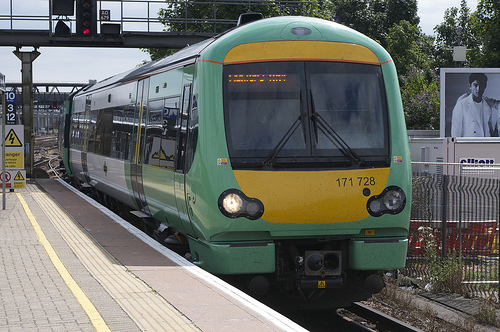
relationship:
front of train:
[223, 39, 394, 221] [58, 15, 414, 310]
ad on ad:
[439, 66, 499, 137] [439, 66, 499, 137]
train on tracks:
[58, 15, 414, 310] [325, 301, 422, 331]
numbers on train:
[333, 174, 378, 187] [58, 15, 414, 310]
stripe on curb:
[14, 189, 112, 331] [0, 242, 166, 331]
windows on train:
[51, 94, 198, 169] [58, 15, 414, 310]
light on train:
[223, 192, 243, 212] [58, 15, 414, 310]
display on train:
[227, 72, 302, 90] [58, 15, 414, 310]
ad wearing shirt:
[439, 66, 499, 137] [450, 94, 492, 137]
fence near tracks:
[411, 161, 499, 303] [325, 301, 422, 331]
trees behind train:
[150, 0, 499, 128] [58, 15, 414, 310]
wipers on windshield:
[261, 88, 361, 169] [224, 62, 391, 171]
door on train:
[128, 77, 149, 213] [58, 15, 414, 310]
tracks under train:
[325, 301, 422, 331] [58, 15, 414, 310]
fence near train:
[411, 161, 499, 303] [58, 15, 414, 310]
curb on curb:
[55, 174, 308, 331] [0, 242, 166, 331]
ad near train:
[439, 66, 499, 137] [58, 15, 414, 310]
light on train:
[383, 186, 402, 210] [58, 15, 414, 310]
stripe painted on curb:
[14, 189, 112, 331] [0, 242, 166, 331]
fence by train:
[411, 161, 499, 303] [58, 15, 414, 310]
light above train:
[82, 27, 91, 36] [58, 15, 414, 310]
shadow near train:
[30, 172, 191, 268] [58, 15, 414, 310]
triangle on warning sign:
[2, 129, 23, 148] [3, 124, 28, 190]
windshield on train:
[224, 62, 391, 171] [58, 15, 414, 310]